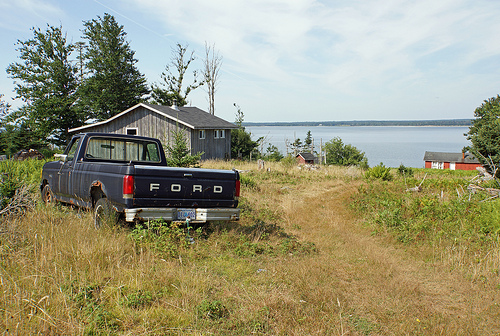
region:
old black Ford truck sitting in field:
[35, 127, 252, 247]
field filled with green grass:
[6, 160, 497, 324]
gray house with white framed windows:
[63, 98, 236, 160]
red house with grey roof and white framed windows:
[424, 145, 493, 174]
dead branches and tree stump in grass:
[405, 166, 498, 206]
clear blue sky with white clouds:
[21, 3, 494, 119]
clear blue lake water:
[258, 128, 498, 166]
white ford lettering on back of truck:
[145, 180, 227, 196]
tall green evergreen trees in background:
[0, 8, 158, 158]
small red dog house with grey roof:
[293, 149, 318, 164]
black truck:
[45, 129, 273, 226]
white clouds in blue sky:
[335, 28, 347, 45]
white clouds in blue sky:
[380, 15, 422, 36]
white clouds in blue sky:
[321, 12, 363, 87]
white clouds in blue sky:
[234, 31, 262, 65]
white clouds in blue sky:
[328, 39, 385, 90]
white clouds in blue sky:
[382, 13, 422, 45]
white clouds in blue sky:
[280, 45, 325, 100]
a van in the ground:
[23, 95, 260, 243]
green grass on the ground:
[363, 170, 499, 227]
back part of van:
[146, 175, 242, 203]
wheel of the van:
[88, 193, 143, 254]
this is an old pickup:
[36, 110, 286, 260]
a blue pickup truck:
[6, 98, 278, 267]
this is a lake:
[235, 108, 496, 183]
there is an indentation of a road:
[291, 173, 417, 333]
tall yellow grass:
[5, 198, 163, 333]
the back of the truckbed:
[127, 159, 250, 219]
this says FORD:
[139, 170, 238, 202]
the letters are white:
[126, 170, 236, 207]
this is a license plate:
[169, 205, 211, 225]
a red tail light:
[116, 173, 139, 200]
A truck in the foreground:
[35, 117, 250, 249]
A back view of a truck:
[24, 122, 256, 250]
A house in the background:
[62, 83, 247, 184]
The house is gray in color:
[63, 80, 248, 178]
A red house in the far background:
[413, 142, 497, 181]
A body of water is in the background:
[246, 113, 483, 169]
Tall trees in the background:
[2, 6, 276, 161]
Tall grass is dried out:
[2, 208, 327, 335]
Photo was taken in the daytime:
[0, 3, 496, 330]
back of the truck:
[99, 145, 264, 238]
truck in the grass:
[3, 117, 268, 249]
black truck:
[28, 120, 248, 240]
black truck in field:
[37, 130, 245, 235]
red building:
[413, 140, 488, 180]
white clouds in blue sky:
[256, 35, 290, 72]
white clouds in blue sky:
[306, 90, 360, 107]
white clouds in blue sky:
[305, 2, 345, 40]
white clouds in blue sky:
[406, 10, 450, 53]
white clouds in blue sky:
[294, 100, 334, 122]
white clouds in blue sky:
[339, 71, 405, 106]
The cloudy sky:
[137, 36, 494, 120]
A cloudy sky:
[4, 44, 494, 121]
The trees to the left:
[3, 35, 234, 146]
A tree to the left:
[0, 30, 239, 146]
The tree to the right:
[453, 83, 498, 179]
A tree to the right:
[451, 82, 498, 205]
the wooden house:
[58, 91, 245, 161]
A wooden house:
[60, 93, 247, 165]